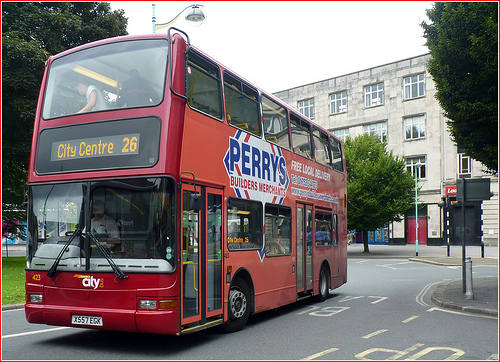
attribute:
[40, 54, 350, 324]
bus — red, tall, huge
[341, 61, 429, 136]
building — stone, red, tall, old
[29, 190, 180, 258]
windshield — clean, clear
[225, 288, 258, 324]
wheel — black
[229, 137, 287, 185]
letters — blue